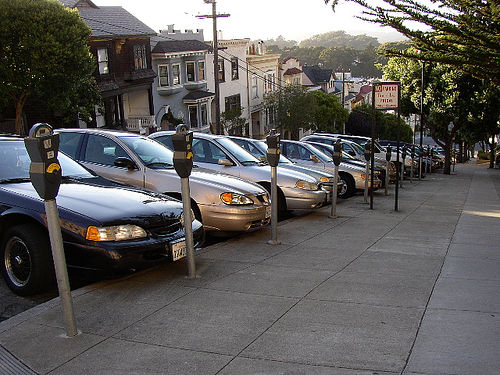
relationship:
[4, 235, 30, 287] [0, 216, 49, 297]
hubcap surrounded by front tire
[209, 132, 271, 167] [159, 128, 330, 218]
windshield on car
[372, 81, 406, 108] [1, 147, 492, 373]
parking sign on sidewalk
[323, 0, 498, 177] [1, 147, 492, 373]
trees down sidewalk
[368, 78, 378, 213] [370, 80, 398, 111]
pole holding sign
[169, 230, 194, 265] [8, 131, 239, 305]
plate on car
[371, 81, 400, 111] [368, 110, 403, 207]
parking sign on pole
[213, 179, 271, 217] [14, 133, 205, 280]
headlight of car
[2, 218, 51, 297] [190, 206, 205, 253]
front tire of black car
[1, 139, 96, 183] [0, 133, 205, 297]
window of black car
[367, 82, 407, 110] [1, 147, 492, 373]
signboard on sidewalk